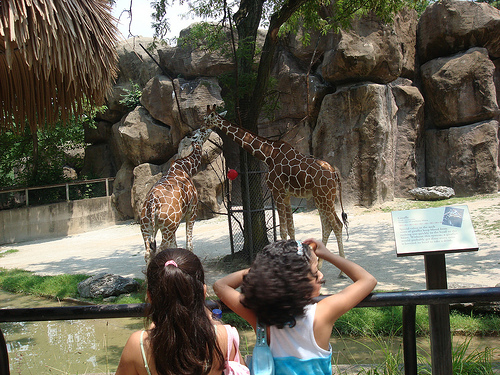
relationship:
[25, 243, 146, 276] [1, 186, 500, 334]
shadow on ground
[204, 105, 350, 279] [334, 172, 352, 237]
giraffe has a tail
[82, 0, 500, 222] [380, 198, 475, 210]
rocks on grass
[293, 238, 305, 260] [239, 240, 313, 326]
headband in hair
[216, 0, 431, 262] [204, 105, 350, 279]
tree behind giraffe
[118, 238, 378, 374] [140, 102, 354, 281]
girl are watching giraffes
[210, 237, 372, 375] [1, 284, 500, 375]
girl leaning on fence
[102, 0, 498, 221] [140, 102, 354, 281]
rocks are behind giraffes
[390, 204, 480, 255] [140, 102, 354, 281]
sign about giraffes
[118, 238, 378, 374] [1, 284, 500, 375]
girl are standing by fence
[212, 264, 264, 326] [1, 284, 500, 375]
arm on fence